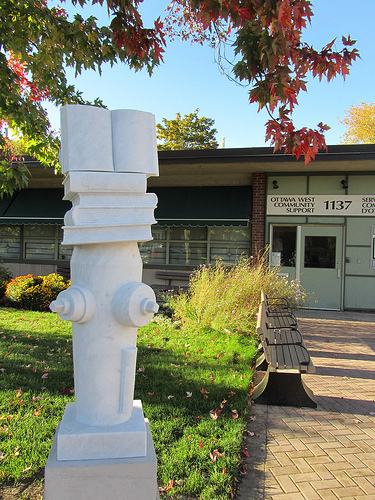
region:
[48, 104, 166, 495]
Statue in front of community center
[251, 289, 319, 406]
Park benches inn front of a building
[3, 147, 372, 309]
Front of a community center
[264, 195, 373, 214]
Sign on a community center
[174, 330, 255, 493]
Fall leaves on the grund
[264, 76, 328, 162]
Red leaves on a tree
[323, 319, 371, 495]
Patterned pavers as a sidewalk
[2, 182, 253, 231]
Awning over some windows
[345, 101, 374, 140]
Yellow leaves on a tree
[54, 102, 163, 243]
Book portion of a statue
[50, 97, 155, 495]
Unusual tall white sculpture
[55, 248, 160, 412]
Middle portion sculpture hydrant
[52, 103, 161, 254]
Four stacked books one open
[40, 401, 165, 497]
Sculpture pedestal base squares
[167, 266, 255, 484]
Fall foliage dry bush leaves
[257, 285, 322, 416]
Wooden bench's resting area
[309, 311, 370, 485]
Walkway pavement inlaid brick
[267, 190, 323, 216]
Ottawa West Community Support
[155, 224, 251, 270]
Louvered windows along building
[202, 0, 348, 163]
Colorful fall foliage hanging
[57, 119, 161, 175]
Open book is made of cement.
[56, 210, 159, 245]
Book made of cement.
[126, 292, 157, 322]
White knob on the fire hydrant.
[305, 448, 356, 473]
The walkway is made of brick.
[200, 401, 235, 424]
Leaves on the ground.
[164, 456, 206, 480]
The grass is green.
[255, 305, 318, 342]
Bench on the side of the walkway.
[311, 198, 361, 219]
1137 above a door.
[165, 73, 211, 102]
The sky is blue.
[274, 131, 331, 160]
Leaves on the tree are red.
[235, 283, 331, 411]
A series of benches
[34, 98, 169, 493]
A white statue with a book on top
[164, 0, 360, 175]
Red leaves on a tree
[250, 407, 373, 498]
Bricks in a sidewalk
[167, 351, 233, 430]
Leaves in the grass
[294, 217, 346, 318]
A door with a window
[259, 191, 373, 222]
A white sign with black writing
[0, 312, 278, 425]
A shadow across a lawn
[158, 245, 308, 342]
A green shrub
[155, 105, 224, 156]
A tree behind the building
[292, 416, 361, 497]
this is a footpath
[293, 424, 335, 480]
the footpath is made with tiles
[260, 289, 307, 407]
this is a bench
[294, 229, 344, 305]
this is a door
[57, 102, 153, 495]
this is a hydrant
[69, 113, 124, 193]
the hydrant is white in color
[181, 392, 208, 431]
this is a section with grass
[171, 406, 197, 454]
the grass is green in color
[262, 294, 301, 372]
the bench is empty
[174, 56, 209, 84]
this is the sky